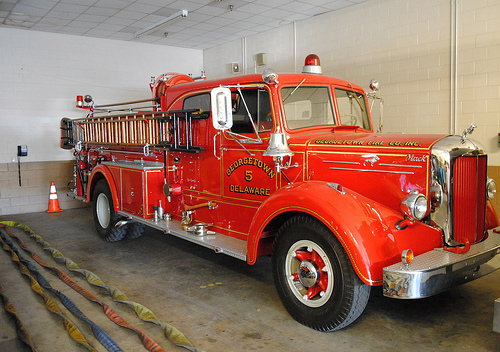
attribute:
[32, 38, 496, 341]
truck — red, yellow, silver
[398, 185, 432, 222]
light — red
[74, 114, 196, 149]
ladder — large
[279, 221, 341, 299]
front tire — black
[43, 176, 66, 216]
cone — orange, white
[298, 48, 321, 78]
light — red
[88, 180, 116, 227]
rear tire — black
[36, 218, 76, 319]
hose — yellow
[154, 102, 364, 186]
fire engine — antique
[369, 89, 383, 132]
mirror — large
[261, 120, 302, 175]
bell — silver, large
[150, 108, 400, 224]
fire truck — vintage, red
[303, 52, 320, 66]
strobe-light — red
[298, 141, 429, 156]
stripes — yellow